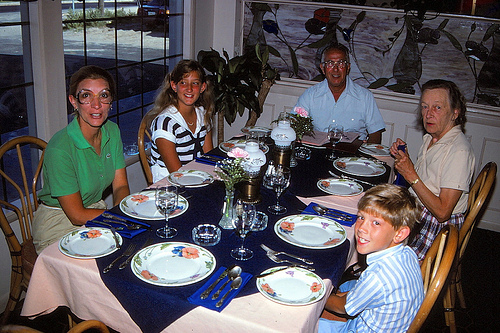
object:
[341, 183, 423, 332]
boy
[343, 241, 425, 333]
shirt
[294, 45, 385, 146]
man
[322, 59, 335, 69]
glasses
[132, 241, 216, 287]
plate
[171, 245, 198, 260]
flower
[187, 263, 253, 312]
napkin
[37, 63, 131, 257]
lady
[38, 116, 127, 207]
shirt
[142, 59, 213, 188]
girl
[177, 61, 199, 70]
hair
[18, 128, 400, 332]
tablecloth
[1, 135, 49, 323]
chair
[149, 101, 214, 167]
shirt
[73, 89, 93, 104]
glasses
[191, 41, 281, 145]
plant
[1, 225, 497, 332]
floor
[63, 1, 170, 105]
window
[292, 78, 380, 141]
shirt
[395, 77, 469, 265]
grandma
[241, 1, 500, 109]
drawing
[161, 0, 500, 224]
wall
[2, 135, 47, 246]
back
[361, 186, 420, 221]
hair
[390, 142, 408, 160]
napkin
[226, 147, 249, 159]
rose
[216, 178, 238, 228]
vase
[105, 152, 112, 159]
logo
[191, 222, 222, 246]
ashtray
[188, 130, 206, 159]
tie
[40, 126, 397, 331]
table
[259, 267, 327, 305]
plate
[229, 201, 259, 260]
goblet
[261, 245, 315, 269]
fork